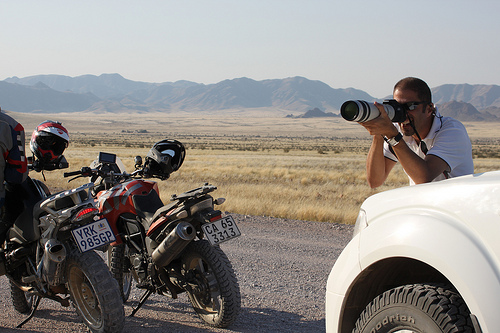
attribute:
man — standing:
[332, 69, 478, 189]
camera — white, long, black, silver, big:
[335, 94, 410, 131]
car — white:
[318, 165, 499, 331]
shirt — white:
[379, 100, 479, 188]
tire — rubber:
[177, 233, 246, 332]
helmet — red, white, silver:
[27, 117, 74, 168]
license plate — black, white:
[198, 211, 245, 251]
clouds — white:
[1, 1, 500, 98]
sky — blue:
[0, 0, 499, 93]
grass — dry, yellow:
[3, 111, 500, 225]